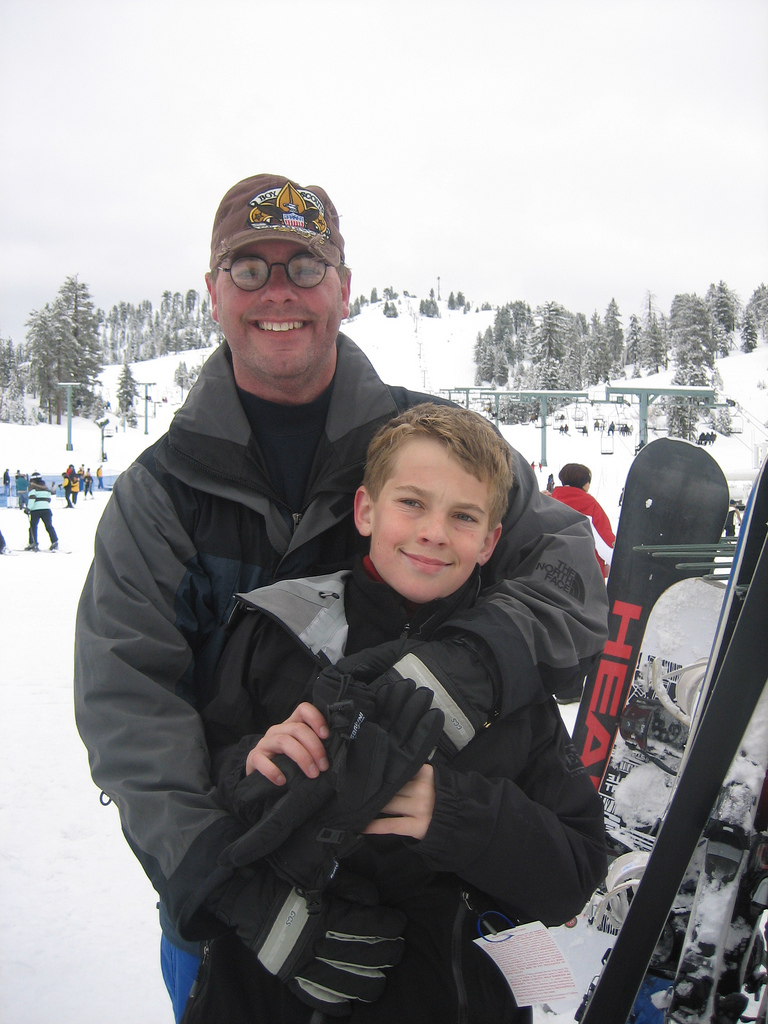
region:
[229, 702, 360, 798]
boy has bare hands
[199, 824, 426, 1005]
gloves that are worn are black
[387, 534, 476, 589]
boy has a smile on face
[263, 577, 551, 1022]
boy is wearing black jacket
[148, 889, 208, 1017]
man is wearing blue pants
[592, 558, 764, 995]
snowboard is black and white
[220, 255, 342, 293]
man is wearing glasses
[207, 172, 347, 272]
A brown hat with a logo on the front of it.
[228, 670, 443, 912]
A pair of black gloves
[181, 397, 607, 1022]
A young blonde headed boy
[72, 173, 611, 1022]
A man hugging a young boy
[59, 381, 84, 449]
A green wooden post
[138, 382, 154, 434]
A green wooden post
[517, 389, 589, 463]
A green wooden post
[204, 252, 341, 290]
A pair of glasses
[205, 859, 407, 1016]
A grey and black glove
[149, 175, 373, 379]
the man is wearing glasses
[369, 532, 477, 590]
the lips are pink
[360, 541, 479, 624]
the mouth is closed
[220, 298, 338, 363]
the teeth are showing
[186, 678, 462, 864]
the boy is holding gloves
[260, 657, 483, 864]
the gloves are black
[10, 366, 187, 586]
the people are skiing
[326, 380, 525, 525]
the boy's hair is brownish blonde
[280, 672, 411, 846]
The boy is holding black gloves in his hand.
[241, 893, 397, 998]
The man is wearing black and gray gloves.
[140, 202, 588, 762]
The man is holding his son around him.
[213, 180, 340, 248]
The man is wearing a cap.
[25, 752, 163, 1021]
The ground is covered in snow.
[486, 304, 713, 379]
The trees are covered with white snow.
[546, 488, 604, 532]
A person is wearing a red jacket.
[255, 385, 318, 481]
The man is wearing a black shirt under the jacket.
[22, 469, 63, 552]
person on snow covered ground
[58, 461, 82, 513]
person on snow covered ground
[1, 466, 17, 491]
person on snow covered ground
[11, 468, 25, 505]
person on snow covered ground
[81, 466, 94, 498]
person on snow covered ground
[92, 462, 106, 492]
person on snow covered ground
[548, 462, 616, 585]
person on snow covered ground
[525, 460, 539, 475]
person on snow covered ground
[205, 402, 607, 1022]
person on snow covered ground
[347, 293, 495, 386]
a snow covered hill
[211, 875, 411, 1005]
a man's black and gray glove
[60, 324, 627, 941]
a man's black and gray jacket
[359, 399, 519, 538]
a boy's short cut hair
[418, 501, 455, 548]
the nose of a boy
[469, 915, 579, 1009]
a red and white piece of paper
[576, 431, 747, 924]
a red and black snowboard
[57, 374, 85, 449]
a tall gray pole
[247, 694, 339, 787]
the hand of a boy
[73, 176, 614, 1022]
tall man with glasses holding boy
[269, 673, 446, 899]
large black cloth glove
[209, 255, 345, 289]
wide rimmed black glasses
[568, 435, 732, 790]
long thin black snowboard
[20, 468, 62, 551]
small short person in snow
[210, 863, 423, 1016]
black and grey glove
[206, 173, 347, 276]
brown cloth cap hat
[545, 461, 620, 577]
woman in red coat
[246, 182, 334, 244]
yellow symbol on hat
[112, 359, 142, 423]
A tree in a field